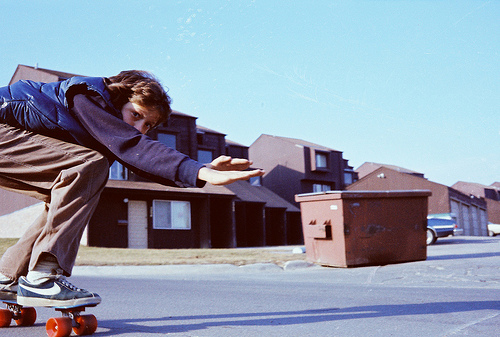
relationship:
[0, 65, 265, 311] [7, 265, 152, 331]
boy on board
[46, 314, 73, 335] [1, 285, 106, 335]
wheel on skateboard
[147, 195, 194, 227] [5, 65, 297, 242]
window on building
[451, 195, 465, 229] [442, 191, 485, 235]
door on garage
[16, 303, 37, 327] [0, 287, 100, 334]
wheel on skateboard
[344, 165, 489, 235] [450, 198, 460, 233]
garages of garages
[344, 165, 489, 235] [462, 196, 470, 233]
garages of garages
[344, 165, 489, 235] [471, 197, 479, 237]
garages of garages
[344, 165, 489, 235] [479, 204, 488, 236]
garages of garages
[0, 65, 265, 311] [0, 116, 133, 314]
boy wearing brown pant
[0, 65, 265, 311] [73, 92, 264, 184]
boy with arm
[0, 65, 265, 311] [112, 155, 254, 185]
boy with arm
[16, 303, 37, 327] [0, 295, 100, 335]
wheel on skateboard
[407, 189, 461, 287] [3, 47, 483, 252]
car in background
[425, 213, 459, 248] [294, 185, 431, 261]
car on dumpster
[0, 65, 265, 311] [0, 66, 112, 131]
boy on vest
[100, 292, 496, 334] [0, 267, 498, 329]
shadow on ground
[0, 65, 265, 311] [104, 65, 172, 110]
boy has hair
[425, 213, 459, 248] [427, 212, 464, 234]
car next to car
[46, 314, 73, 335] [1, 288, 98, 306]
wheel on skateboard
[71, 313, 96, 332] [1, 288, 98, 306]
wheel on skateboard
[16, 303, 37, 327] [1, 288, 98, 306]
wheel on skateboard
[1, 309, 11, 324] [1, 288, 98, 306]
wheel on skateboard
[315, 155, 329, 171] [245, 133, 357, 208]
window on apartments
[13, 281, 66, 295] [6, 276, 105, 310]
logo on shoe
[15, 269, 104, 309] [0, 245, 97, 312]
boy'sfoot on boy'sfoot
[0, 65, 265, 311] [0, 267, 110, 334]
boy on skateboard